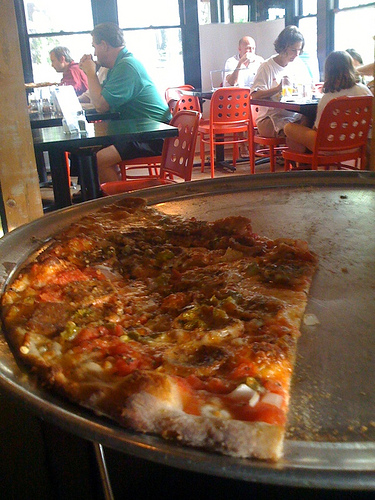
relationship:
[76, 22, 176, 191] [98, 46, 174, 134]
man wearing green shirt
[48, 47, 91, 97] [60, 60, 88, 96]
man wearing red shirt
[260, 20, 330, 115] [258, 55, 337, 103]
girl in shirt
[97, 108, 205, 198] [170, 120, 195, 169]
chair with pattern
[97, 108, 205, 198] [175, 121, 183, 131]
chair with hole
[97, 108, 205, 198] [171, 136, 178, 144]
chair with hole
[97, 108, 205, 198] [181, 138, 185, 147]
chair with hole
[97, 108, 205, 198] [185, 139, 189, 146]
chair with hole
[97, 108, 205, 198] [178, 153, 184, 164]
chair with hole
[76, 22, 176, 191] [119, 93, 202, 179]
man sitting on chair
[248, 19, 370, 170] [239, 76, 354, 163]
people sitting at table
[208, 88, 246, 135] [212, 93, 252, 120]
chair with circles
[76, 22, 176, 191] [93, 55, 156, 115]
man in shirt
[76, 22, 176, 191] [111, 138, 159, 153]
man in shorts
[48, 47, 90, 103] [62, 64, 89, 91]
man with shirt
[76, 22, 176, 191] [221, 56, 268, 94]
man in shirt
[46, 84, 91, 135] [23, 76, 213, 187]
menu on table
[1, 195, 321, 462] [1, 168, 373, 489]
pizza on pan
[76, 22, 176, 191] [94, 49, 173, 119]
man in green shirt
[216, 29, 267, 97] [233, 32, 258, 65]
man with head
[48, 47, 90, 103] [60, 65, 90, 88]
man with red shirt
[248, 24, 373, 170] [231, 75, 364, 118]
people at table